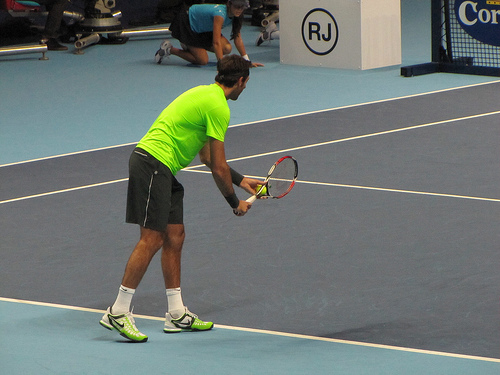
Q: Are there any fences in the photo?
A: No, there are no fences.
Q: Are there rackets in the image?
A: Yes, there is a racket.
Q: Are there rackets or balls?
A: Yes, there is a racket.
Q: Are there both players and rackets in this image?
A: Yes, there are both a racket and a player.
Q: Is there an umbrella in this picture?
A: No, there are no umbrellas.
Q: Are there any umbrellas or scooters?
A: No, there are no umbrellas or scooters.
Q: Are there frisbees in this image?
A: No, there are no frisbees.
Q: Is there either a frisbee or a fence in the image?
A: No, there are no frisbees or fences.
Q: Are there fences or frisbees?
A: No, there are no frisbees or fences.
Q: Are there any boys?
A: No, there are no boys.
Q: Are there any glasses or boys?
A: No, there are no boys or glasses.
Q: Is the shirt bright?
A: Yes, the shirt is bright.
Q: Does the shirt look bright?
A: Yes, the shirt is bright.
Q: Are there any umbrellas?
A: No, there are no umbrellas.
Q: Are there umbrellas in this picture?
A: No, there are no umbrellas.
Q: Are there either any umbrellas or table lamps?
A: No, there are no umbrellas or table lamps.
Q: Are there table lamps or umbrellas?
A: No, there are no umbrellas or table lamps.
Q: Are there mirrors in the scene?
A: No, there are no mirrors.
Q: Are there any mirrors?
A: No, there are no mirrors.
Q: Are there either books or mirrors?
A: No, there are no mirrors or books.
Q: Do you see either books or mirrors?
A: No, there are no mirrors or books.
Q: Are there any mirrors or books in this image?
A: No, there are no mirrors or books.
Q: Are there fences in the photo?
A: No, there are no fences.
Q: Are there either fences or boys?
A: No, there are no fences or boys.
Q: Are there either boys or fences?
A: No, there are no fences or boys.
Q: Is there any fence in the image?
A: No, there are no fences.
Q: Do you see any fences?
A: No, there are no fences.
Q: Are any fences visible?
A: No, there are no fences.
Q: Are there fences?
A: No, there are no fences.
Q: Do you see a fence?
A: No, there are no fences.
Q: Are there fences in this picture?
A: No, there are no fences.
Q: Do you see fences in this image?
A: No, there are no fences.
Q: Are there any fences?
A: No, there are no fences.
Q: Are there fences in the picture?
A: No, there are no fences.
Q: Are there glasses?
A: No, there are no glasses.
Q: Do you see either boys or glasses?
A: No, there are no glasses or boys.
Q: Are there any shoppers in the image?
A: No, there are no shoppers.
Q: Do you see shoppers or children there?
A: No, there are no shoppers or children.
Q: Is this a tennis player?
A: Yes, this is a tennis player.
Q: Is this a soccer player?
A: No, this is a tennis player.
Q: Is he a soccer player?
A: No, this is a tennis player.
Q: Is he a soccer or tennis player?
A: This is a tennis player.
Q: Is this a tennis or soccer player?
A: This is a tennis player.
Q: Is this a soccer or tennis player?
A: This is a tennis player.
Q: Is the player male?
A: Yes, the player is male.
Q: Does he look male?
A: Yes, the player is male.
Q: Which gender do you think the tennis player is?
A: The player is male.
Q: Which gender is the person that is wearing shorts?
A: The player is male.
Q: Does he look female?
A: No, the player is male.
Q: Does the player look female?
A: No, the player is male.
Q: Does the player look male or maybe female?
A: The player is male.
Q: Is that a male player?
A: Yes, that is a male player.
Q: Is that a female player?
A: No, that is a male player.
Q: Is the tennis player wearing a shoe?
A: Yes, the player is wearing a shoe.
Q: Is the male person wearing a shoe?
A: Yes, the player is wearing a shoe.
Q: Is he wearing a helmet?
A: No, the player is wearing a shoe.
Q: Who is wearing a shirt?
A: The player is wearing a shirt.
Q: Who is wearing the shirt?
A: The player is wearing a shirt.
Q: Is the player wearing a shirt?
A: Yes, the player is wearing a shirt.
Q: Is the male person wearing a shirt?
A: Yes, the player is wearing a shirt.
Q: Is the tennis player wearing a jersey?
A: No, the player is wearing a shirt.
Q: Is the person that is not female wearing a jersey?
A: No, the player is wearing a shirt.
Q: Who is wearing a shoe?
A: The player is wearing a shoe.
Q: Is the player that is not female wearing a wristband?
A: No, the player is wearing a shoe.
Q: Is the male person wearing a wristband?
A: No, the player is wearing a shoe.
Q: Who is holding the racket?
A: The player is holding the racket.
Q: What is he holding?
A: The player is holding the tennis racket.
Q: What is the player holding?
A: The player is holding the tennis racket.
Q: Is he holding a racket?
A: Yes, the player is holding a racket.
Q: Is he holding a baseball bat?
A: No, the player is holding a racket.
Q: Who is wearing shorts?
A: The player is wearing shorts.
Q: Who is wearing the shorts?
A: The player is wearing shorts.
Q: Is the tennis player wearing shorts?
A: Yes, the player is wearing shorts.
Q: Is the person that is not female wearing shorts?
A: Yes, the player is wearing shorts.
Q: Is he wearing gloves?
A: No, the player is wearing shorts.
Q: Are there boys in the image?
A: No, there are no boys.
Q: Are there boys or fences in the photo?
A: No, there are no boys or fences.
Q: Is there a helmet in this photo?
A: No, there are no helmets.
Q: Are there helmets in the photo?
A: No, there are no helmets.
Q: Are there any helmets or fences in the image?
A: No, there are no helmets or fences.